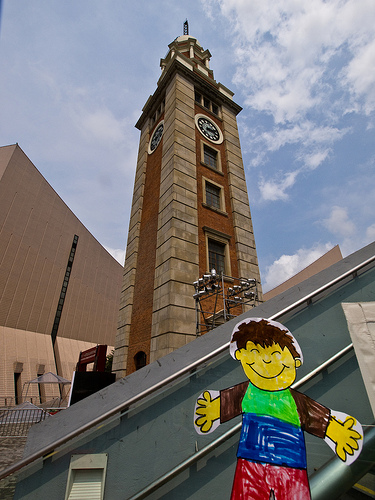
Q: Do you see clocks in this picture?
A: Yes, there is a clock.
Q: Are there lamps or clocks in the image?
A: Yes, there is a clock.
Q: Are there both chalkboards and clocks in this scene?
A: No, there is a clock but no chalkboards.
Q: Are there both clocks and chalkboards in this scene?
A: No, there is a clock but no chalkboards.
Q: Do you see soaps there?
A: No, there are no soaps.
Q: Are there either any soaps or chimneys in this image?
A: No, there are no soaps or chimneys.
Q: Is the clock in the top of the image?
A: Yes, the clock is in the top of the image.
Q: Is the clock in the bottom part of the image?
A: No, the clock is in the top of the image.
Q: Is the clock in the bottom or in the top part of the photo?
A: The clock is in the top of the image.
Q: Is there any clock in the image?
A: Yes, there is a clock.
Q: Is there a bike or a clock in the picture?
A: Yes, there is a clock.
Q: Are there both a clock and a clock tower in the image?
A: Yes, there are both a clock and a clock tower.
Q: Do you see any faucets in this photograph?
A: No, there are no faucets.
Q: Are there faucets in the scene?
A: No, there are no faucets.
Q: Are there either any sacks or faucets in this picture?
A: No, there are no faucets or sacks.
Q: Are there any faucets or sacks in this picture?
A: No, there are no faucets or sacks.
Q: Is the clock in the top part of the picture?
A: Yes, the clock is in the top of the image.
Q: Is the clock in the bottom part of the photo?
A: No, the clock is in the top of the image.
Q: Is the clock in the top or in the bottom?
A: The clock is in the top of the image.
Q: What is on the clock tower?
A: The clock is on the clock tower.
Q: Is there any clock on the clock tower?
A: Yes, there is a clock on the clock tower.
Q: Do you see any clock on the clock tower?
A: Yes, there is a clock on the clock tower.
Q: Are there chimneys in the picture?
A: No, there are no chimneys.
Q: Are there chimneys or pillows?
A: No, there are no chimneys or pillows.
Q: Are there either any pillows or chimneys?
A: No, there are no chimneys or pillows.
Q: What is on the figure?
A: The marker is on the figure.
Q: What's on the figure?
A: The marker is on the figure.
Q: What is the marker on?
A: The marker is on the figure.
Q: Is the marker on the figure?
A: Yes, the marker is on the figure.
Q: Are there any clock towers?
A: Yes, there is a clock tower.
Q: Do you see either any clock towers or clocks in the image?
A: Yes, there is a clock tower.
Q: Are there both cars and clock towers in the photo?
A: No, there is a clock tower but no cars.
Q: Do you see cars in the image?
A: No, there are no cars.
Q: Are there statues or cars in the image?
A: No, there are no cars or statues.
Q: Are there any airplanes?
A: No, there are no airplanes.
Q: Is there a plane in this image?
A: No, there are no airplanes.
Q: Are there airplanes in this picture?
A: No, there are no airplanes.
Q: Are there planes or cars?
A: No, there are no planes or cars.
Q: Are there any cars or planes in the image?
A: No, there are no planes or cars.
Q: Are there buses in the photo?
A: No, there are no buses.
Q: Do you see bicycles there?
A: No, there are no bicycles.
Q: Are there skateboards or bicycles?
A: No, there are no bicycles or skateboards.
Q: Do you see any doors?
A: Yes, there is a door.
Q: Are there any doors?
A: Yes, there is a door.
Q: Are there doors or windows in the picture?
A: Yes, there is a door.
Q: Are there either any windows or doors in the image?
A: Yes, there is a door.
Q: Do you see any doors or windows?
A: Yes, there is a door.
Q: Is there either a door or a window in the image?
A: Yes, there is a door.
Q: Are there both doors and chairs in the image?
A: No, there is a door but no chairs.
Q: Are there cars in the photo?
A: No, there are no cars.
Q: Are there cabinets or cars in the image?
A: No, there are no cars or cabinets.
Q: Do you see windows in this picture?
A: Yes, there is a window.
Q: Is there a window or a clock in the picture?
A: Yes, there is a window.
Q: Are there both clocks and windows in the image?
A: Yes, there are both a window and a clock.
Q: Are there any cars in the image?
A: No, there are no cars.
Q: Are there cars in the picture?
A: No, there are no cars.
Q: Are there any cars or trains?
A: No, there are no cars or trains.